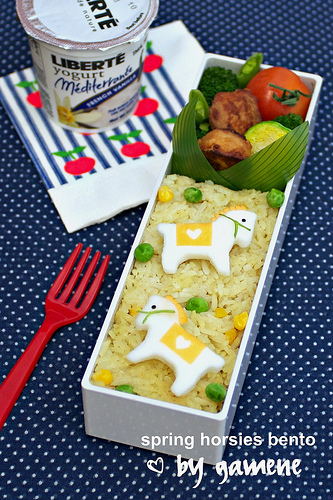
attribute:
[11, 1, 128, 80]
yogurt — liberte, potted, vanilla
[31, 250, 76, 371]
fork — shiny, red, plastic, beside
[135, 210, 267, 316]
candy — shaped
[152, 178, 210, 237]
corn — kernels, yellow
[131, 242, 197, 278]
pea — green, cooked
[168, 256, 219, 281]
rice — yellow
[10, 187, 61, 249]
tablecloth — blue, spotted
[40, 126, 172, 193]
napkin — here, under, colorful, decorative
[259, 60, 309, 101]
tomato — ripe, red, orange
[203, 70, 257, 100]
broccoli — here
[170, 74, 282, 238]
plate — rectangular, white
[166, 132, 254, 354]
food — shaped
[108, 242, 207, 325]
peas — here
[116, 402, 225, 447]
container — white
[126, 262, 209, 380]
decoration — horsey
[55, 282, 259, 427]
box — bento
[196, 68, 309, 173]
vegetables — inside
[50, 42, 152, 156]
vanilla — french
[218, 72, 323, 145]
fruit — red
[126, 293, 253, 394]
horse — small